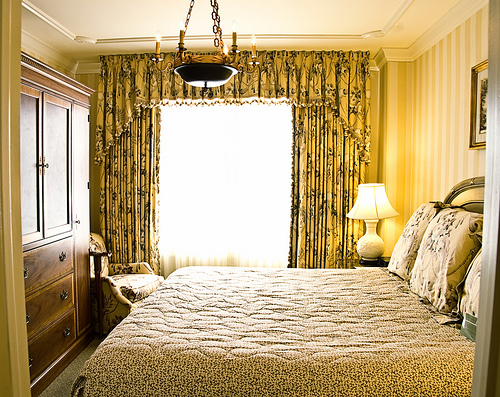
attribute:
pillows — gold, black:
[386, 198, 483, 331]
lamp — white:
[345, 181, 398, 259]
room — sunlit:
[0, 0, 499, 394]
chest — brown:
[18, 50, 90, 393]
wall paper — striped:
[366, 3, 485, 257]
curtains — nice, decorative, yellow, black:
[95, 50, 370, 269]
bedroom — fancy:
[1, 2, 499, 394]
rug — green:
[35, 343, 96, 394]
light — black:
[150, 0, 260, 94]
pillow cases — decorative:
[385, 200, 483, 341]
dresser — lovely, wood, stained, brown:
[18, 50, 94, 394]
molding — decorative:
[18, 2, 488, 68]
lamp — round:
[347, 180, 395, 256]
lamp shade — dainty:
[345, 180, 398, 218]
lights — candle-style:
[153, 30, 256, 58]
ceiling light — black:
[154, 3, 257, 88]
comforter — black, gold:
[93, 265, 475, 393]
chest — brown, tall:
[20, 50, 100, 396]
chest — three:
[24, 58, 86, 390]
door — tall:
[74, 110, 101, 334]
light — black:
[154, 0, 259, 87]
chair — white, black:
[92, 236, 158, 321]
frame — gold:
[467, 59, 487, 149]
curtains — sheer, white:
[162, 102, 292, 266]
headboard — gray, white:
[436, 175, 488, 214]